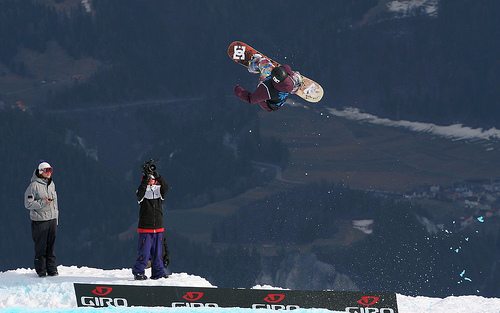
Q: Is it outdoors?
A: Yes, it is outdoors.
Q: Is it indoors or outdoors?
A: It is outdoors.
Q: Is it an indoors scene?
A: No, it is outdoors.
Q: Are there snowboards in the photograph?
A: Yes, there is a snowboard.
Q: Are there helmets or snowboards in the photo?
A: Yes, there is a snowboard.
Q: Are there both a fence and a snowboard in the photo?
A: No, there is a snowboard but no fences.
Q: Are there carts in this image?
A: No, there are no carts.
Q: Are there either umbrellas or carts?
A: No, there are no carts or umbrellas.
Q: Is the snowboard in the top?
A: Yes, the snowboard is in the top of the image.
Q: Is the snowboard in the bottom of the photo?
A: No, the snowboard is in the top of the image.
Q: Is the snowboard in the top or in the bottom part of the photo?
A: The snowboard is in the top of the image.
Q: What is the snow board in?
A: The snow board is in the air.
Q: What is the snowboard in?
A: The snow board is in the air.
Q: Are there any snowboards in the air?
A: Yes, there is a snowboard in the air.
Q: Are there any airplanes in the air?
A: No, there is a snowboard in the air.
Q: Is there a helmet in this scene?
A: Yes, there is a helmet.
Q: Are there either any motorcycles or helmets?
A: Yes, there is a helmet.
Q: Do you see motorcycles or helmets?
A: Yes, there is a helmet.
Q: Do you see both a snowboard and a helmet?
A: Yes, there are both a helmet and a snowboard.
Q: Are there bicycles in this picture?
A: No, there are no bicycles.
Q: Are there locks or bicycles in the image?
A: No, there are no bicycles or locks.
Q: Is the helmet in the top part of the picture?
A: Yes, the helmet is in the top of the image.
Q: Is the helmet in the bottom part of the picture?
A: No, the helmet is in the top of the image.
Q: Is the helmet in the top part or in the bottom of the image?
A: The helmet is in the top of the image.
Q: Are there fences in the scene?
A: No, there are no fences.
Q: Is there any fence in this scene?
A: No, there are no fences.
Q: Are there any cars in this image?
A: No, there are no cars.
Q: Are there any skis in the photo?
A: No, there are no skis.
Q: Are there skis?
A: No, there are no skis.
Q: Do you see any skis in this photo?
A: No, there are no skis.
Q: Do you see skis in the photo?
A: No, there are no skis.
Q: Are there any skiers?
A: No, there are no skiers.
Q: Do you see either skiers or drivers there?
A: No, there are no skiers or drivers.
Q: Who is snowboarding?
A: The man is snowboarding.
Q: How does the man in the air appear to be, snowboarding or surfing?
A: The man is snowboarding.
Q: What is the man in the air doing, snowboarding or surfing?
A: The man is snowboarding.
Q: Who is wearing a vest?
A: The man is wearing a vest.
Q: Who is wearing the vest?
A: The man is wearing a vest.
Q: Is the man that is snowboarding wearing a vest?
A: Yes, the man is wearing a vest.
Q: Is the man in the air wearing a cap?
A: No, the man is wearing a vest.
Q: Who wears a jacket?
A: The man wears a jacket.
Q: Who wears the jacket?
A: The man wears a jacket.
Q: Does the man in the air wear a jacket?
A: Yes, the man wears a jacket.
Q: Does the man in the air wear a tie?
A: No, the man wears a jacket.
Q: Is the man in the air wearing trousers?
A: Yes, the man is wearing trousers.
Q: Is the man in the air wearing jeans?
A: No, the man is wearing trousers.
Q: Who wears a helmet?
A: The man wears a helmet.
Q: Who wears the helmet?
A: The man wears a helmet.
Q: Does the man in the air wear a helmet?
A: Yes, the man wears a helmet.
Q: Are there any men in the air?
A: Yes, there is a man in the air.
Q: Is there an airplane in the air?
A: No, there is a man in the air.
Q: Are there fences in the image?
A: No, there are no fences.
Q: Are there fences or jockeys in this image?
A: No, there are no fences or jockeys.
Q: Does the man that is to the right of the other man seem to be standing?
A: Yes, the man is standing.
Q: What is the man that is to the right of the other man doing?
A: The man is standing.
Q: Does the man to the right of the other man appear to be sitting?
A: No, the man is standing.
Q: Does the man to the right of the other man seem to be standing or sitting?
A: The man is standing.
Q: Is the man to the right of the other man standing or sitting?
A: The man is standing.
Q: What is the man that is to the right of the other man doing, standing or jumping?
A: The man is standing.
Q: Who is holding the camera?
A: The man is holding the camera.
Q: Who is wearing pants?
A: The man is wearing pants.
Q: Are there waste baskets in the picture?
A: No, there are no waste baskets.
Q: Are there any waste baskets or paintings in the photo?
A: No, there are no waste baskets or paintings.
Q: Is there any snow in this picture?
A: Yes, there is snow.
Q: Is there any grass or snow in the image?
A: Yes, there is snow.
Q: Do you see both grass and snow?
A: No, there is snow but no grass.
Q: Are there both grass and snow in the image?
A: No, there is snow but no grass.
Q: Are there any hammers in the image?
A: No, there are no hammers.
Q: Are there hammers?
A: No, there are no hammers.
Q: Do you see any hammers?
A: No, there are no hammers.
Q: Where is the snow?
A: The snow is on the hill.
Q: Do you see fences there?
A: No, there are no fences.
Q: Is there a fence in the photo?
A: No, there are no fences.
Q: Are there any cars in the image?
A: No, there are no cars.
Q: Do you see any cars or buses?
A: No, there are no cars or buses.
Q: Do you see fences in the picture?
A: No, there are no fences.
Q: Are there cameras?
A: Yes, there is a camera.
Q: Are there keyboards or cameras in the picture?
A: Yes, there is a camera.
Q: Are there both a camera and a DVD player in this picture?
A: No, there is a camera but no DVD players.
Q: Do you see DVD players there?
A: No, there are no DVD players.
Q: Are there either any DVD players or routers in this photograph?
A: No, there are no DVD players or routers.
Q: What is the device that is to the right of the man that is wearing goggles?
A: The device is a camera.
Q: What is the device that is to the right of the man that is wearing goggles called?
A: The device is a camera.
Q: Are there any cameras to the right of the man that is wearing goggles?
A: Yes, there is a camera to the right of the man.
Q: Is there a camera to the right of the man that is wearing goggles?
A: Yes, there is a camera to the right of the man.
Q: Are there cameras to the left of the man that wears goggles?
A: No, the camera is to the right of the man.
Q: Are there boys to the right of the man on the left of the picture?
A: No, there is a camera to the right of the man.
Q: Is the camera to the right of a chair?
A: No, the camera is to the right of a man.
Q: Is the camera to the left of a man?
A: No, the camera is to the right of a man.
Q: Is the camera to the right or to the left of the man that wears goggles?
A: The camera is to the right of the man.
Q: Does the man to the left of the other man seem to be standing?
A: Yes, the man is standing.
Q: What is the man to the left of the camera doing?
A: The man is standing.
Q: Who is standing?
A: The man is standing.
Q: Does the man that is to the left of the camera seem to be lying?
A: No, the man is standing.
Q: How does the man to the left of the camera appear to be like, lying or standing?
A: The man is standing.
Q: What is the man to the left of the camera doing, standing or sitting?
A: The man is standing.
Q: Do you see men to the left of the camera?
A: Yes, there is a man to the left of the camera.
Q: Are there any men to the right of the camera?
A: No, the man is to the left of the camera.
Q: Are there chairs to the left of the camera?
A: No, there is a man to the left of the camera.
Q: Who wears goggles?
A: The man wears goggles.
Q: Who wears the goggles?
A: The man wears goggles.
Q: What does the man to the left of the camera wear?
A: The man wears goggles.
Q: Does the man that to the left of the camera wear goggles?
A: Yes, the man wears goggles.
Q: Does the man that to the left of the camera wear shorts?
A: No, the man wears goggles.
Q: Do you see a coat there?
A: Yes, there is a coat.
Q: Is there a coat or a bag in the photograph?
A: Yes, there is a coat.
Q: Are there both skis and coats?
A: No, there is a coat but no skis.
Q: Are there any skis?
A: No, there are no skis.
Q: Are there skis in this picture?
A: No, there are no skis.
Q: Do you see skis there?
A: No, there are no skis.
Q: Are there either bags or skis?
A: No, there are no skis or bags.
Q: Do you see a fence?
A: No, there are no fences.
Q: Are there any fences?
A: No, there are no fences.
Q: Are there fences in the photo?
A: No, there are no fences.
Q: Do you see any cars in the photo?
A: No, there are no cars.